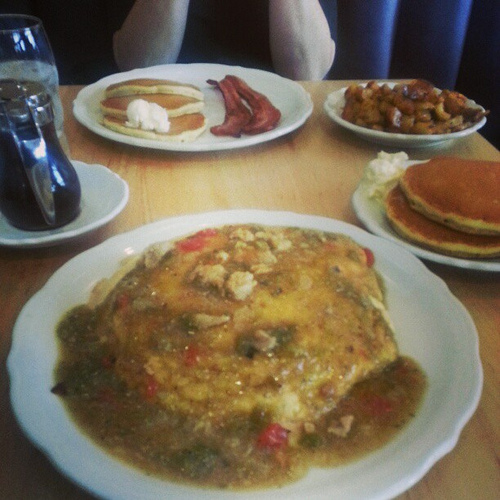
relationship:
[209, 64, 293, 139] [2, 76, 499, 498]
meat on table